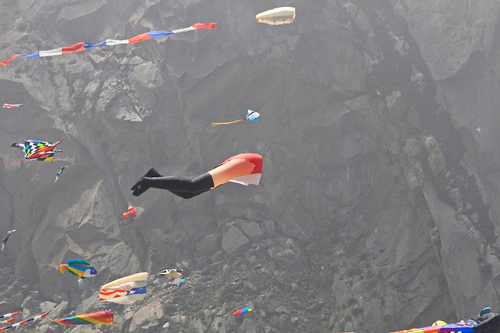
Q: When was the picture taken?
A: During the day.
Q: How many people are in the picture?
A: None.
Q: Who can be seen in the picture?
A: No one.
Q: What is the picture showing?
A: Kites.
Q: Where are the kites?
A: In the sky.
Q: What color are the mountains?
A: Gray.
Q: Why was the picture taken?
A: To capture the kites.